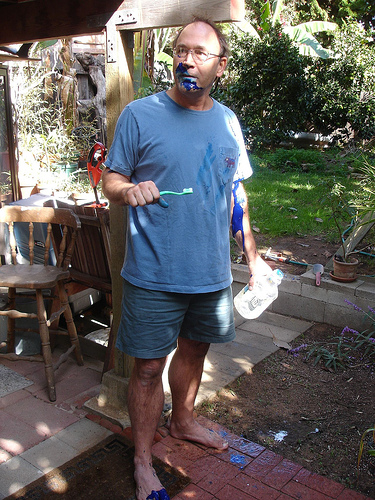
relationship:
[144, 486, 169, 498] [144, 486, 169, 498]
paint on paint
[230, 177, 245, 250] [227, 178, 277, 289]
paint on arm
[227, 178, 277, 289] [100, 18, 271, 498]
arm on man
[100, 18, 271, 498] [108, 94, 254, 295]
man wearing blue shirt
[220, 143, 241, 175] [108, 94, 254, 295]
paint on blue shirt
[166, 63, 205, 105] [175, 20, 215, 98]
blue paint on face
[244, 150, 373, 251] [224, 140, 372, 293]
grass in ground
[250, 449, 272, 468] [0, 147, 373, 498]
bricks on ground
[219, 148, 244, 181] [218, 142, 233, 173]
pocket in front of shirt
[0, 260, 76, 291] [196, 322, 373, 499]
seat on ground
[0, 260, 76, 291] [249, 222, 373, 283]
seat on ground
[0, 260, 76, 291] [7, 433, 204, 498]
seat on ground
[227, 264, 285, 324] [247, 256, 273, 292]
bottle in hand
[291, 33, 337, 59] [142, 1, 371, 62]
leaf on plant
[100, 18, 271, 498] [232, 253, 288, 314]
man holding bottle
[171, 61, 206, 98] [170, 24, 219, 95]
blue paint on face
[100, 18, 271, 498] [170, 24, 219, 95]
man has face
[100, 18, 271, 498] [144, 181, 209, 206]
man holding toothbrush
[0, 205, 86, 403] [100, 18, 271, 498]
chair behind man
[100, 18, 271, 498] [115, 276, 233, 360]
man wearing shorts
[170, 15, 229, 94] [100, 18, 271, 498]
head of man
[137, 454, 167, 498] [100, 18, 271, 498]
barefoot of man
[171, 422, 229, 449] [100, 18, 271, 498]
barefoot of man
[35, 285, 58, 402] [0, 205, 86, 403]
leg of chair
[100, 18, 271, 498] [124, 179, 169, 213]
man has hand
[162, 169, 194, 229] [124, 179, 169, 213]
toothbrush in mans hand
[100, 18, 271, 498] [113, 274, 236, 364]
man wearing shorts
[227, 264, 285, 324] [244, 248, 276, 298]
bottle in hand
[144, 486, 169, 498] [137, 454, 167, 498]
paint on barefoot